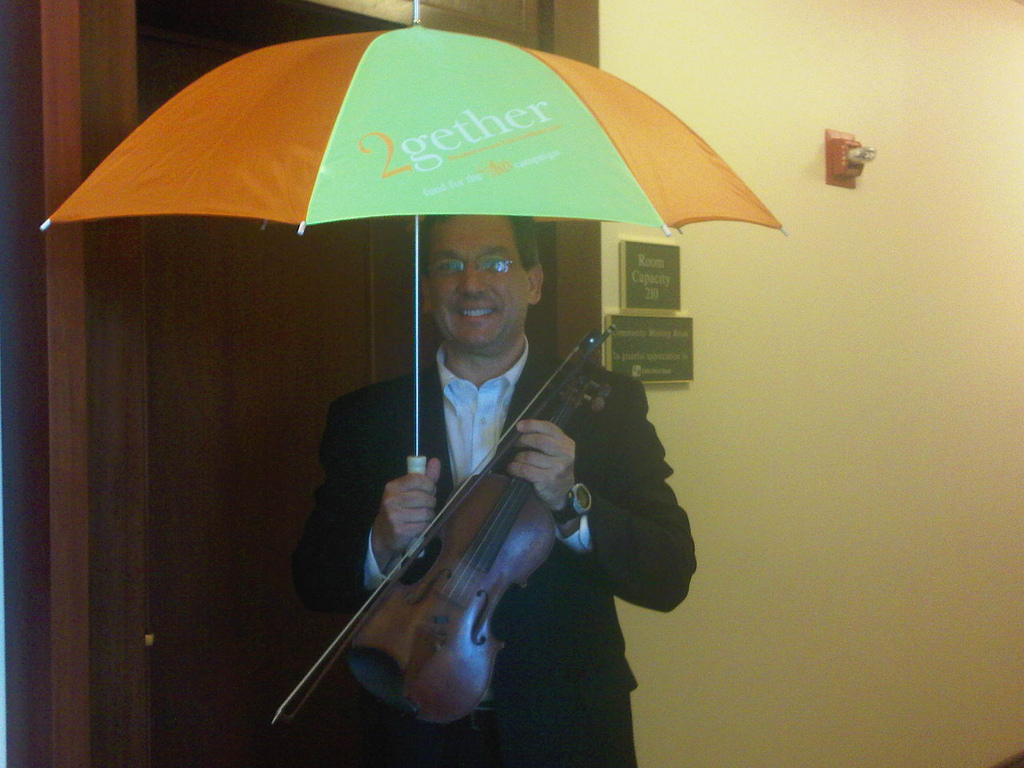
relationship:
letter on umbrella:
[522, 90, 559, 149] [31, 0, 794, 552]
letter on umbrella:
[419, 120, 472, 160] [25, 19, 788, 272]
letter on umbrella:
[425, 122, 473, 174] [25, 19, 788, 272]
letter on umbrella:
[499, 101, 541, 151] [25, 19, 788, 272]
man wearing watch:
[287, 214, 697, 768] [546, 475, 592, 528]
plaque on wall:
[619, 239, 686, 313] [596, 0, 1022, 763]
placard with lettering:
[604, 314, 697, 386] [614, 323, 692, 341]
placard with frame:
[604, 314, 697, 386] [606, 309, 695, 322]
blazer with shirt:
[287, 340, 700, 720] [431, 350, 533, 474]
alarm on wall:
[826, 128, 874, 189] [596, 0, 1022, 763]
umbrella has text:
[31, 0, 794, 552] [359, 93, 565, 182]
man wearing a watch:
[287, 214, 697, 768] [553, 477, 599, 540]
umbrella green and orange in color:
[186, 110, 692, 231] [171, 203, 208, 236]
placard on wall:
[604, 314, 697, 386] [590, 295, 843, 468]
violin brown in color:
[214, 434, 644, 768] [341, 654, 415, 768]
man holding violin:
[287, 214, 697, 768] [270, 294, 627, 757]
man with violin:
[287, 214, 697, 768] [276, 282, 642, 741]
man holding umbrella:
[287, 214, 697, 768] [31, 0, 794, 552]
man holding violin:
[307, 227, 694, 750] [248, 310, 616, 741]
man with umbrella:
[307, 227, 694, 750] [10, 16, 797, 531]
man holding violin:
[287, 214, 697, 768] [257, 329, 662, 746]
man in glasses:
[287, 214, 697, 768] [442, 255, 531, 288]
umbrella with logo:
[31, 0, 794, 552] [354, 93, 551, 191]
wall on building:
[635, 39, 983, 763] [11, 14, 979, 762]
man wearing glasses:
[287, 214, 697, 768] [436, 245, 525, 282]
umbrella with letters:
[31, 0, 794, 552] [354, 117, 571, 165]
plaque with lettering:
[619, 239, 686, 313] [619, 238, 684, 332]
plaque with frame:
[619, 239, 686, 313] [598, 215, 735, 414]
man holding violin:
[287, 214, 697, 768] [276, 282, 642, 741]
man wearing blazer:
[287, 214, 697, 768] [287, 340, 700, 720]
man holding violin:
[287, 214, 697, 768] [338, 323, 622, 730]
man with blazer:
[197, 201, 694, 670] [287, 340, 700, 720]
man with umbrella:
[197, 201, 694, 670] [92, 16, 825, 250]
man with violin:
[197, 201, 694, 670] [353, 292, 727, 720]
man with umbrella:
[287, 214, 697, 768] [53, 33, 888, 356]